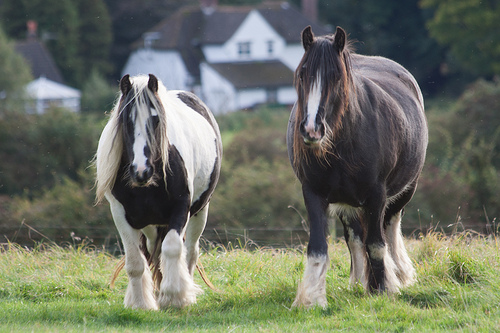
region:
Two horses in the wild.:
[61, 29, 496, 331]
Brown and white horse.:
[39, 24, 313, 329]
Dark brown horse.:
[253, 4, 455, 326]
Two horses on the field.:
[79, 21, 496, 279]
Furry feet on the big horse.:
[54, 216, 241, 328]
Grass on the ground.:
[26, 171, 182, 318]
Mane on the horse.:
[233, 8, 488, 237]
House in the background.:
[127, 12, 425, 148]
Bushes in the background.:
[10, 94, 95, 274]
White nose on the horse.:
[296, 66, 335, 148]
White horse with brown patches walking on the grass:
[89, 63, 223, 320]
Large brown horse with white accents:
[285, 27, 430, 313]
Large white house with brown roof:
[117, 0, 337, 120]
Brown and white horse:
[95, 72, 223, 316]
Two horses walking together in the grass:
[91, 22, 426, 316]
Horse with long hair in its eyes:
[287, 24, 428, 313]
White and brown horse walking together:
[92, 24, 439, 315]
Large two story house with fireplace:
[116, 2, 346, 124]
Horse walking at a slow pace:
[83, 70, 220, 315]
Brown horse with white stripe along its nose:
[287, 23, 427, 317]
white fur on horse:
[187, 150, 192, 167]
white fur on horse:
[194, 135, 201, 138]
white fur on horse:
[168, 287, 180, 293]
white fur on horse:
[307, 264, 312, 278]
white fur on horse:
[346, 243, 358, 260]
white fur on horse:
[116, 217, 125, 231]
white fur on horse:
[102, 148, 109, 154]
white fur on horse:
[140, 124, 149, 165]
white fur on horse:
[179, 108, 195, 126]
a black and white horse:
[242, 13, 438, 305]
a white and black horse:
[63, 60, 264, 322]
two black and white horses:
[51, 32, 488, 298]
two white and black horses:
[83, 62, 494, 319]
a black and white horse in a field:
[247, 38, 489, 322]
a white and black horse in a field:
[36, 75, 245, 300]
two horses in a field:
[62, 51, 492, 303]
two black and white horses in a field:
[88, 52, 436, 291]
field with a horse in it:
[3, 188, 263, 320]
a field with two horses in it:
[74, 194, 468, 323]